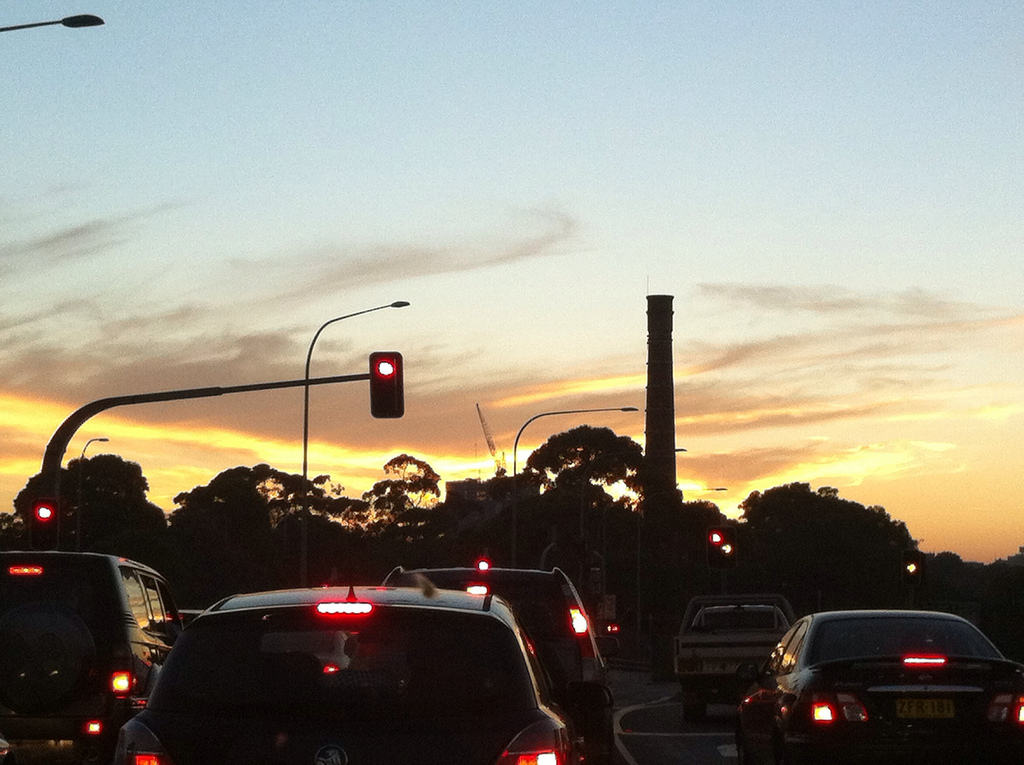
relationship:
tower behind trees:
[640, 281, 695, 616] [16, 430, 1021, 636]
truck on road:
[673, 593, 793, 692] [18, 603, 989, 738]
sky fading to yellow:
[14, 31, 993, 332] [20, 385, 973, 526]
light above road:
[369, 352, 404, 418] [12, 531, 1021, 748]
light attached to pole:
[369, 352, 404, 418] [33, 379, 390, 539]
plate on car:
[859, 703, 993, 732] [739, 588, 979, 731]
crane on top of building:
[469, 396, 515, 476] [441, 463, 550, 531]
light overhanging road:
[369, 352, 404, 418] [116, 623, 989, 740]